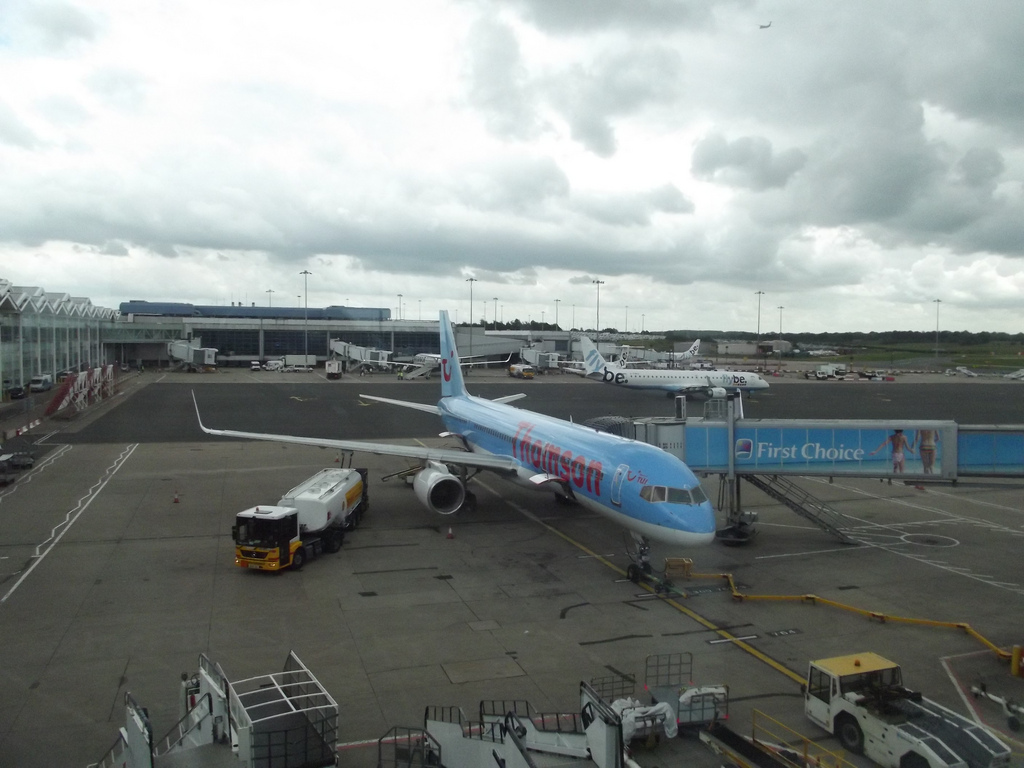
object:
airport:
[580, 336, 769, 399]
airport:
[0, 319, 446, 443]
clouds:
[660, 134, 849, 260]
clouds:
[255, 93, 433, 177]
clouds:
[106, 86, 278, 221]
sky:
[298, 110, 465, 174]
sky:
[841, 53, 1002, 239]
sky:
[76, 56, 219, 159]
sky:
[547, 126, 805, 278]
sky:
[816, 80, 939, 270]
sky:
[107, 74, 315, 221]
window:
[640, 484, 653, 501]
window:
[651, 484, 668, 502]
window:
[688, 486, 707, 504]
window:
[666, 487, 691, 504]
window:
[640, 484, 667, 501]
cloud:
[449, 22, 537, 143]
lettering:
[512, 421, 600, 495]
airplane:
[191, 310, 717, 547]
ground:
[0, 373, 1024, 768]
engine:
[413, 458, 467, 514]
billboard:
[684, 416, 957, 479]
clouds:
[0, 0, 1024, 337]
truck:
[232, 467, 371, 570]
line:
[613, 567, 815, 688]